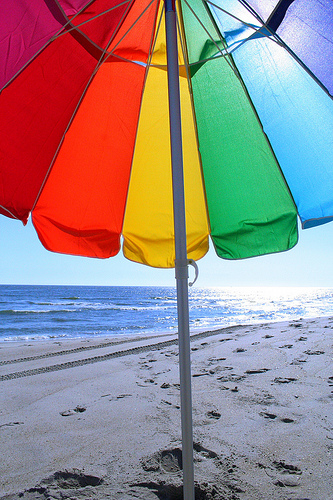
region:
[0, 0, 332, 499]
the colorful opened umbrella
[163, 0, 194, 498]
the pole for the umbrella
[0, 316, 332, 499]
the sand on the beach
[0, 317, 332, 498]
the markings in the sand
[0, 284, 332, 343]
the large body of water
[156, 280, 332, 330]
the sun reflecting on the water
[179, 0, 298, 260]
the green part of the umbrella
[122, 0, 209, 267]
the yellow part on the umbrella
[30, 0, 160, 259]
the orange part on the umbrella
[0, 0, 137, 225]
the red part on the umbrella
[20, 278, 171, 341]
blue ocean water at beach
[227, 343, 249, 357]
footprint in the sand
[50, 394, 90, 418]
foot print of person in sand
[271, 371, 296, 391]
footprint of man in sand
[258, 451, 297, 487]
barefootprint in the sand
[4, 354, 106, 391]
tire tracks in the sand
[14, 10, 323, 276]
rainbow colored umbrella on beach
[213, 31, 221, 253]
green color of umbrella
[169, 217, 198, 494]
metal pole from umbrella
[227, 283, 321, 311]
sun reflecting off the water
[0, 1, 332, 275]
THE UMBRELLA IS RAINBOW COLORED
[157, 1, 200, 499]
THE POLE IS SILVER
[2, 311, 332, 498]
THE BEACH HAS TRACKS IN THE SAND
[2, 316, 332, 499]
THE SAND IS WET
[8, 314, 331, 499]
THE TRACKS ARE FROM PEOPLE WALKING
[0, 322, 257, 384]
THE TRACKS ARE FROM A VEHICLE DRIVING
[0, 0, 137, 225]
THIS IS A RED SECTION ON THE UMBRELLA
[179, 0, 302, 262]
THE UMBRELLA HAS A GREEN SECTION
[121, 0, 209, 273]
THIS IS A YELLOW SECTION OF CLOTH ON THE UMBRELLA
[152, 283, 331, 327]
THE WATER IS SPARKLING WHERE IT IS REFLECTING THE SUNLIGHT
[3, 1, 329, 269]
top of multi-colored umbrella on the beach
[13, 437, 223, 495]
foot prints in the sand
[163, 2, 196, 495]
pole to hold up umbrella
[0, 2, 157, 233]
braces connecting pole to fabric of umbrella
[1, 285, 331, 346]
bright blue body of water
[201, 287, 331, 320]
sun reflecting off waterr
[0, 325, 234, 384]
tracks from a motorized vehicle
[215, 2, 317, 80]
sun on other side of the umbrella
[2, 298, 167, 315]
small wave in the water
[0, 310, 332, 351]
spot where water meets the beach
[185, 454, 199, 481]
[part of a post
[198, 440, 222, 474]
part of a boundary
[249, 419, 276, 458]
part of a beach